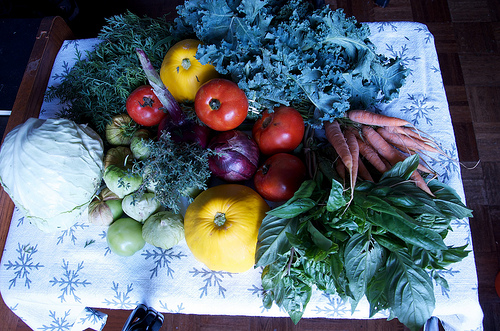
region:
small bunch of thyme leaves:
[268, 279, 322, 316]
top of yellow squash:
[203, 202, 238, 240]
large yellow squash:
[190, 185, 288, 272]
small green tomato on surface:
[93, 216, 157, 269]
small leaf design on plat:
[125, 247, 199, 296]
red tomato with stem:
[186, 87, 257, 139]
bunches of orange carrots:
[321, 92, 429, 194]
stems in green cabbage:
[12, 111, 109, 218]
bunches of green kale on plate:
[216, 28, 374, 129]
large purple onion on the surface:
[190, 119, 287, 193]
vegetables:
[7, 6, 491, 327]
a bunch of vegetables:
[4, 3, 499, 325]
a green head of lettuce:
[2, 116, 108, 236]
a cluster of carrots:
[316, 104, 441, 205]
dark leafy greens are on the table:
[177, 0, 472, 320]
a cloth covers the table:
[7, 14, 472, 329]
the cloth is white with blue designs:
[3, 18, 482, 328]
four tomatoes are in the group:
[120, 79, 315, 203]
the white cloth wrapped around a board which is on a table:
[12, 8, 498, 323]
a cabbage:
[1, 113, 108, 243]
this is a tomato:
[198, 88, 245, 130]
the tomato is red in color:
[223, 96, 240, 118]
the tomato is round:
[191, 86, 239, 121]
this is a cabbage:
[18, 122, 75, 209]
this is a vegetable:
[220, 14, 348, 86]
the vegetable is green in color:
[262, 61, 309, 83]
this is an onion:
[220, 137, 255, 174]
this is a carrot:
[323, 122, 350, 158]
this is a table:
[401, 37, 433, 120]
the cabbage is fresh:
[33, 136, 72, 201]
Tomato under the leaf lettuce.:
[190, 80, 249, 129]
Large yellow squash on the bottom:
[181, 184, 268, 274]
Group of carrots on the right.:
[322, 105, 451, 203]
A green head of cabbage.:
[1, 116, 101, 233]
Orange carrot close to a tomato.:
[323, 114, 353, 172]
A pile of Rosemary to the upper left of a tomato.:
[40, 11, 166, 127]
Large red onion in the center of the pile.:
[202, 132, 262, 184]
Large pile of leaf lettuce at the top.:
[171, 1, 411, 126]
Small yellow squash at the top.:
[158, 39, 213, 103]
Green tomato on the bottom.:
[104, 221, 145, 258]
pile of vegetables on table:
[56, 46, 427, 276]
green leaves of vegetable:
[287, 201, 447, 316]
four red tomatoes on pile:
[126, 84, 308, 194]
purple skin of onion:
[207, 121, 260, 188]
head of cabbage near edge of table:
[4, 108, 115, 232]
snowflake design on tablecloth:
[47, 248, 103, 310]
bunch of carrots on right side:
[311, 87, 449, 202]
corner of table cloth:
[389, 14, 450, 62]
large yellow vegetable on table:
[181, 180, 271, 281]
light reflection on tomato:
[218, 102, 238, 129]